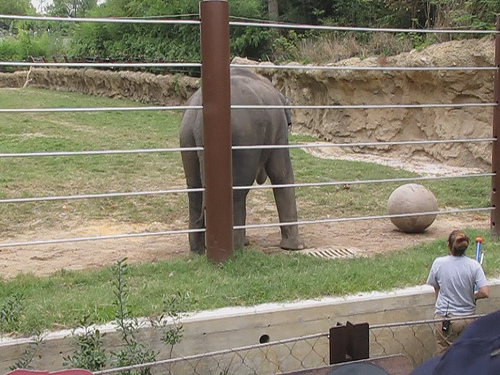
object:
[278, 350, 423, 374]
gate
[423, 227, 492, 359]
human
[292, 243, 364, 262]
grate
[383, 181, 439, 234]
ball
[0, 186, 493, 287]
dirt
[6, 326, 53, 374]
plant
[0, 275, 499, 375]
cement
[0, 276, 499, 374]
wall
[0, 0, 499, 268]
fence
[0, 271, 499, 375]
enclosure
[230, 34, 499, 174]
rock wall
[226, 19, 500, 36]
wires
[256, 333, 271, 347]
hole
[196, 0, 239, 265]
pole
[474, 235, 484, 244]
orange ball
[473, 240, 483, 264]
blue pole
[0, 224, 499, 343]
grass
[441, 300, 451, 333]
radio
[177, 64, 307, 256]
elephant